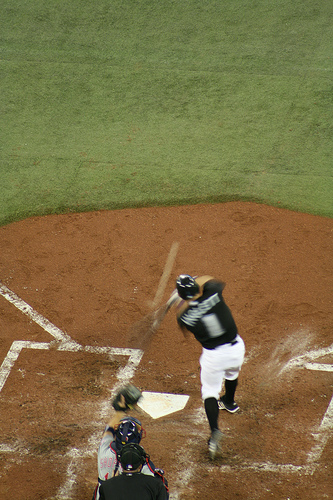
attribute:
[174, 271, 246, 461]
man — in swinging motion, hitter, wearing black, wearing white, hitting ball, catcher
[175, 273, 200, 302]
helmet — black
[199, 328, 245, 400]
pants — white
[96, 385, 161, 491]
man — catcher, trying to catch ball, wearing uniform, catching baseball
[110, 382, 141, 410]
mitt — black, on hand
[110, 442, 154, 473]
vest — black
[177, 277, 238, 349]
shirt — white, black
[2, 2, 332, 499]
field — green, open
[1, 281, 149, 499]
line — white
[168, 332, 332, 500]
line — white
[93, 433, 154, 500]
shirt — grey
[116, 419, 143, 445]
helmet — blue, masked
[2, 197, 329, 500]
dirt — footprinted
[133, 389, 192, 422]
home base — white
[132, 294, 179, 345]
bat — in motion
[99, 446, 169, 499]
umpire — crouching, wearing black, watching baseball